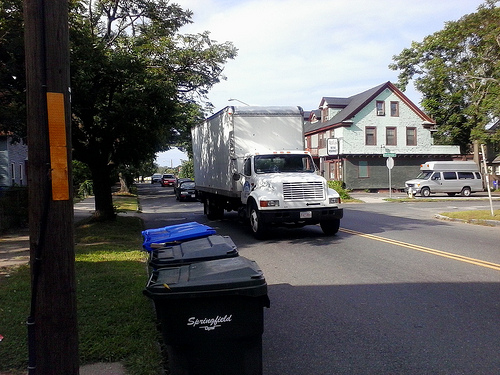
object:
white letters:
[187, 314, 233, 331]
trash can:
[141, 221, 217, 253]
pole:
[23, 0, 80, 374]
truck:
[190, 105, 344, 239]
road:
[136, 235, 499, 375]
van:
[403, 160, 484, 197]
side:
[347, 192, 500, 203]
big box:
[190, 105, 306, 197]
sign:
[383, 153, 396, 199]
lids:
[145, 255, 265, 293]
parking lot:
[347, 160, 499, 227]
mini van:
[161, 174, 178, 187]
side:
[0, 184, 165, 374]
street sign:
[383, 153, 396, 158]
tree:
[0, 0, 238, 223]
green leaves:
[82, 19, 91, 28]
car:
[174, 178, 197, 202]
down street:
[136, 194, 204, 214]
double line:
[338, 227, 499, 271]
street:
[132, 183, 500, 373]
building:
[303, 81, 461, 194]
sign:
[327, 138, 339, 156]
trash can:
[142, 256, 270, 375]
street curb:
[0, 183, 164, 374]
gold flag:
[47, 92, 69, 200]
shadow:
[340, 207, 455, 238]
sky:
[152, 0, 487, 169]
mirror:
[233, 173, 241, 181]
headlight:
[259, 197, 340, 207]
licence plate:
[300, 210, 312, 218]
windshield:
[244, 154, 315, 176]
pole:
[389, 169, 392, 198]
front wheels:
[319, 219, 340, 236]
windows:
[406, 126, 417, 146]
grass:
[0, 183, 169, 374]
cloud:
[168, 0, 486, 113]